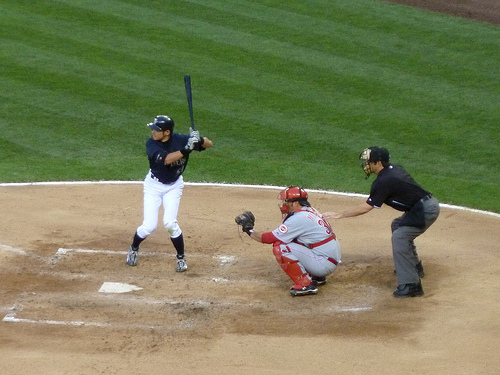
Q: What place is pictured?
A: It is a field.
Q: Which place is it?
A: It is a field.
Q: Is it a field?
A: Yes, it is a field.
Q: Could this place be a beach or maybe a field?
A: It is a field.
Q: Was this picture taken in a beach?
A: No, the picture was taken in a field.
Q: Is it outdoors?
A: Yes, it is outdoors.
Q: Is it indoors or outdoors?
A: It is outdoors.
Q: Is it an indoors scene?
A: No, it is outdoors.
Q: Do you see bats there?
A: Yes, there is a bat.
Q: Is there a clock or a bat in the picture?
A: Yes, there is a bat.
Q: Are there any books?
A: No, there are no books.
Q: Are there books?
A: No, there are no books.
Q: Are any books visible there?
A: No, there are no books.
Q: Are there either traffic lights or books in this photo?
A: No, there are no books or traffic lights.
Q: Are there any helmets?
A: Yes, there is a helmet.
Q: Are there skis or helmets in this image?
A: Yes, there is a helmet.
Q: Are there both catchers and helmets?
A: Yes, there are both a helmet and a catcher.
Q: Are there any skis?
A: No, there are no skis.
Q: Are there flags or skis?
A: No, there are no skis or flags.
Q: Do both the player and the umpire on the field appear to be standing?
A: Yes, both the player and the umpire are standing.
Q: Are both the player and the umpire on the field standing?
A: Yes, both the player and the umpire are standing.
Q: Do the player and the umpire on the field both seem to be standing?
A: Yes, both the player and the umpire are standing.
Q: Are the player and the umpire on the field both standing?
A: Yes, both the player and the umpire are standing.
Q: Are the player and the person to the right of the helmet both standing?
A: Yes, both the player and the umpire are standing.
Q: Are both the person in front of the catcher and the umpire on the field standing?
A: Yes, both the player and the umpire are standing.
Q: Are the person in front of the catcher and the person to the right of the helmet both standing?
A: Yes, both the player and the umpire are standing.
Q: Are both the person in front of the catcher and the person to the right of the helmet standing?
A: Yes, both the player and the umpire are standing.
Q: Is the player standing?
A: Yes, the player is standing.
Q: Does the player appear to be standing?
A: Yes, the player is standing.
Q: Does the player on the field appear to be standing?
A: Yes, the player is standing.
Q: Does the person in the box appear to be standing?
A: Yes, the player is standing.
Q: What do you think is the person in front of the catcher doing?
A: The player is standing.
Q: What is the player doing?
A: The player is standing.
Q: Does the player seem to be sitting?
A: No, the player is standing.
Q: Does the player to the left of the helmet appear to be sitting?
A: No, the player is standing.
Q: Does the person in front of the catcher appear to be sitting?
A: No, the player is standing.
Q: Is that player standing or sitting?
A: The player is standing.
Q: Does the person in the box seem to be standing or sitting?
A: The player is standing.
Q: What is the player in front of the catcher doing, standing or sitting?
A: The player is standing.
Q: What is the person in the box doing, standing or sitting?
A: The player is standing.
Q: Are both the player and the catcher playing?
A: Yes, both the player and the catcher are playing.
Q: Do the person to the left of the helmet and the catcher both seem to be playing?
A: Yes, both the player and the catcher are playing.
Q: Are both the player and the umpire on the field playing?
A: Yes, both the player and the umpire are playing.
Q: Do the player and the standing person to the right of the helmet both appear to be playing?
A: Yes, both the player and the umpire are playing.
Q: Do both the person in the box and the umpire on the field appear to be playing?
A: Yes, both the player and the umpire are playing.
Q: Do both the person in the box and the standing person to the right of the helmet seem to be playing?
A: Yes, both the player and the umpire are playing.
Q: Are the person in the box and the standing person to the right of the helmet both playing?
A: Yes, both the player and the umpire are playing.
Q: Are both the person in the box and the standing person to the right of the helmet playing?
A: Yes, both the player and the umpire are playing.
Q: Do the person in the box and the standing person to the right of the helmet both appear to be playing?
A: Yes, both the player and the umpire are playing.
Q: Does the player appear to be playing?
A: Yes, the player is playing.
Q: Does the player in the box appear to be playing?
A: Yes, the player is playing.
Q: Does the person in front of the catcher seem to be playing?
A: Yes, the player is playing.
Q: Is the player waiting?
A: No, the player is playing.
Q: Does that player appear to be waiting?
A: No, the player is playing.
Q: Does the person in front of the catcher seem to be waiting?
A: No, the player is playing.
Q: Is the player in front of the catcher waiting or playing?
A: The player is playing.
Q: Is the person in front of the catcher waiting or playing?
A: The player is playing.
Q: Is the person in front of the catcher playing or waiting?
A: The player is playing.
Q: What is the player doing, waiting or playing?
A: The player is playing.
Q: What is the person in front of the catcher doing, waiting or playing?
A: The player is playing.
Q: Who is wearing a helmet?
A: The player is wearing a helmet.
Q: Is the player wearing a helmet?
A: Yes, the player is wearing a helmet.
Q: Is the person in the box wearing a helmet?
A: Yes, the player is wearing a helmet.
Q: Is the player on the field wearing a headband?
A: No, the player is wearing a helmet.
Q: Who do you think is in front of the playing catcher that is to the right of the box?
A: The player is in front of the catcher.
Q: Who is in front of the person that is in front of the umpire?
A: The player is in front of the catcher.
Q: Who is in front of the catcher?
A: The player is in front of the catcher.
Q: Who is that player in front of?
A: The player is in front of the catcher.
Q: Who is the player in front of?
A: The player is in front of the catcher.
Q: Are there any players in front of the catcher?
A: Yes, there is a player in front of the catcher.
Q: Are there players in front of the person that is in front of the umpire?
A: Yes, there is a player in front of the catcher.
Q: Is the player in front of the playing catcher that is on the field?
A: Yes, the player is in front of the catcher.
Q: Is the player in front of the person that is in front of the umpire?
A: Yes, the player is in front of the catcher.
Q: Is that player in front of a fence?
A: No, the player is in front of the catcher.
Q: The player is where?
A: The player is on the field.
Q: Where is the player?
A: The player is on the field.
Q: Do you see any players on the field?
A: Yes, there is a player on the field.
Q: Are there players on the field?
A: Yes, there is a player on the field.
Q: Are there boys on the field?
A: No, there is a player on the field.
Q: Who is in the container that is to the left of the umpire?
A: The player is in the box.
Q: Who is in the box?
A: The player is in the box.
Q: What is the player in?
A: The player is in the box.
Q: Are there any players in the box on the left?
A: Yes, there is a player in the box.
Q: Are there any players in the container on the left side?
A: Yes, there is a player in the box.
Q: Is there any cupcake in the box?
A: No, there is a player in the box.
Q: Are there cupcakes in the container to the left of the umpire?
A: No, there is a player in the box.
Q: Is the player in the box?
A: Yes, the player is in the box.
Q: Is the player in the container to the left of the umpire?
A: Yes, the player is in the box.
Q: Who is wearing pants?
A: The player is wearing pants.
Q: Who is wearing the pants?
A: The player is wearing pants.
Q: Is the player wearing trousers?
A: Yes, the player is wearing trousers.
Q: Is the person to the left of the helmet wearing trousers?
A: Yes, the player is wearing trousers.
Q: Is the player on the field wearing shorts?
A: No, the player is wearing trousers.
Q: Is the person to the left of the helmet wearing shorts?
A: No, the player is wearing trousers.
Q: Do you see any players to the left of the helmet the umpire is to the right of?
A: Yes, there is a player to the left of the helmet.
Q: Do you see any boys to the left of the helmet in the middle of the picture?
A: No, there is a player to the left of the helmet.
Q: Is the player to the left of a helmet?
A: Yes, the player is to the left of a helmet.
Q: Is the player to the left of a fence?
A: No, the player is to the left of a helmet.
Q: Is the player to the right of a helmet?
A: No, the player is to the left of a helmet.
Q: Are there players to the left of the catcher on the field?
A: Yes, there is a player to the left of the catcher.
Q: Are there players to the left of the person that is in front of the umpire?
A: Yes, there is a player to the left of the catcher.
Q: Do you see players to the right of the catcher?
A: No, the player is to the left of the catcher.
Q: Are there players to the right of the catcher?
A: No, the player is to the left of the catcher.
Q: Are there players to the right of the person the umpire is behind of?
A: No, the player is to the left of the catcher.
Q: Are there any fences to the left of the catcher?
A: No, there is a player to the left of the catcher.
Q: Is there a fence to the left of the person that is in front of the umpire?
A: No, there is a player to the left of the catcher.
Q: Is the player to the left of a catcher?
A: Yes, the player is to the left of a catcher.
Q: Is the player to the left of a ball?
A: No, the player is to the left of a catcher.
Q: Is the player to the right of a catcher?
A: No, the player is to the left of a catcher.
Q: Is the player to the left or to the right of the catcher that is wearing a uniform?
A: The player is to the left of the catcher.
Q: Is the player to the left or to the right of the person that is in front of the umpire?
A: The player is to the left of the catcher.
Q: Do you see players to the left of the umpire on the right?
A: Yes, there is a player to the left of the umpire.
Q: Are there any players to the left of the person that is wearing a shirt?
A: Yes, there is a player to the left of the umpire.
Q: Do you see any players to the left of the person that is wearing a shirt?
A: Yes, there is a player to the left of the umpire.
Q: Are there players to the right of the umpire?
A: No, the player is to the left of the umpire.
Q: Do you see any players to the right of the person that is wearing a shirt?
A: No, the player is to the left of the umpire.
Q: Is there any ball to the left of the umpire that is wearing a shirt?
A: No, there is a player to the left of the umpire.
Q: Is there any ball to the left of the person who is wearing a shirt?
A: No, there is a player to the left of the umpire.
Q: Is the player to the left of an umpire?
A: Yes, the player is to the left of an umpire.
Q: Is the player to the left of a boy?
A: No, the player is to the left of an umpire.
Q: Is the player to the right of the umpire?
A: No, the player is to the left of the umpire.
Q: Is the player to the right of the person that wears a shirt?
A: No, the player is to the left of the umpire.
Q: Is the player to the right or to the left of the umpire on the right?
A: The player is to the left of the umpire.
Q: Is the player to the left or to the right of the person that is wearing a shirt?
A: The player is to the left of the umpire.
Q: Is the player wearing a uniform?
A: Yes, the player is wearing a uniform.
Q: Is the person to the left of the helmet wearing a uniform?
A: Yes, the player is wearing a uniform.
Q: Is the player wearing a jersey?
A: No, the player is wearing a uniform.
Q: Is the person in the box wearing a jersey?
A: No, the player is wearing a uniform.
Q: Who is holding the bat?
A: The player is holding the bat.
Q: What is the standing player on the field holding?
A: The player is holding the bat.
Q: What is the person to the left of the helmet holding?
A: The player is holding the bat.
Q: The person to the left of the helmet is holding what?
A: The player is holding the bat.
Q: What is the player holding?
A: The player is holding the bat.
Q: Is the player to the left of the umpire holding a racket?
A: No, the player is holding the bat.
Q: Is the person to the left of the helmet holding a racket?
A: No, the player is holding the bat.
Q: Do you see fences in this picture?
A: No, there are no fences.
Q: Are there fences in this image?
A: No, there are no fences.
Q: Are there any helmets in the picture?
A: Yes, there is a helmet.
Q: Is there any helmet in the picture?
A: Yes, there is a helmet.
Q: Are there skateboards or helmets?
A: Yes, there is a helmet.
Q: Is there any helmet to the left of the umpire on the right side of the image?
A: Yes, there is a helmet to the left of the umpire.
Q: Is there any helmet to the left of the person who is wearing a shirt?
A: Yes, there is a helmet to the left of the umpire.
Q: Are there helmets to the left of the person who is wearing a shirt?
A: Yes, there is a helmet to the left of the umpire.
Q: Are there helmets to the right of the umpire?
A: No, the helmet is to the left of the umpire.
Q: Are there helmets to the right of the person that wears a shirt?
A: No, the helmet is to the left of the umpire.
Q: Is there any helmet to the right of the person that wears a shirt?
A: No, the helmet is to the left of the umpire.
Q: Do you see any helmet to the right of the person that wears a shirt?
A: No, the helmet is to the left of the umpire.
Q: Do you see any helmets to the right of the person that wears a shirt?
A: No, the helmet is to the left of the umpire.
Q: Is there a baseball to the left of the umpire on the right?
A: No, there is a helmet to the left of the umpire.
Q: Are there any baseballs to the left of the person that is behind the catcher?
A: No, there is a helmet to the left of the umpire.